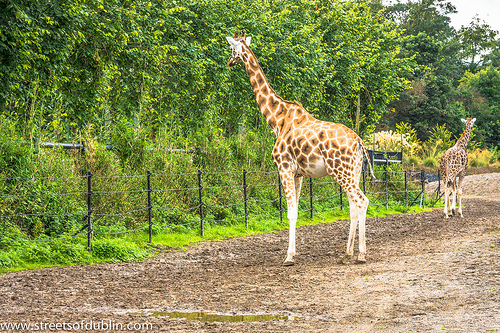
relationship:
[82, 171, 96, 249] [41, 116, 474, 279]
post of fence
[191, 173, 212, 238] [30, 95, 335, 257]
post of fence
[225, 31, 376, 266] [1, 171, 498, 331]
animal standing in mud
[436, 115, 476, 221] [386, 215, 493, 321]
animal standing in dirt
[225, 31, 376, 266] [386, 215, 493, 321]
animal on dirt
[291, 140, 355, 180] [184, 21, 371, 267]
spots on giraffe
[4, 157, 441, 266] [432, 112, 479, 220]
wire fence in front of giraffe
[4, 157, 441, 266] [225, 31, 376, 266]
wire fence in front of animal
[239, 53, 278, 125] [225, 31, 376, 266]
neck on animal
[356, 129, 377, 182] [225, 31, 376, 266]
tail on back of animal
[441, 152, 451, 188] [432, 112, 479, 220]
tail on back of giraffe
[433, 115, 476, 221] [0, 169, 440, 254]
animal explores fence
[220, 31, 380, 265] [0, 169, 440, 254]
animal explores fence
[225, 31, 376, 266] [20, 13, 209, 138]
animal looking into woods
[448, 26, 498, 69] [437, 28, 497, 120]
sky patch seen through trees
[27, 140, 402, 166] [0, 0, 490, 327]
pipe running through area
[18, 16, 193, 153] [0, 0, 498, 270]
foliage of woods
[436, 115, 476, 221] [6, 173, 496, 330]
animal walking down trail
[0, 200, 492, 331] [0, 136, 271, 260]
dirt trail along fence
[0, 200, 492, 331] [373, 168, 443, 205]
dirt trail along fence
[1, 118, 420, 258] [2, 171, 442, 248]
vegetation on other side fence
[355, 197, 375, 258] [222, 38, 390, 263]
leg on giraffe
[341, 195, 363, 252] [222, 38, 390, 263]
leg on giraffe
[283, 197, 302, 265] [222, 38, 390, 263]
leg on giraffe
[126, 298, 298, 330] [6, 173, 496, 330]
puddle on trail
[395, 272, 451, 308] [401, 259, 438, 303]
ground has part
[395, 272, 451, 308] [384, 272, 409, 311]
ground has part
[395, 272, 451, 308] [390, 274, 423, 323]
ground has part